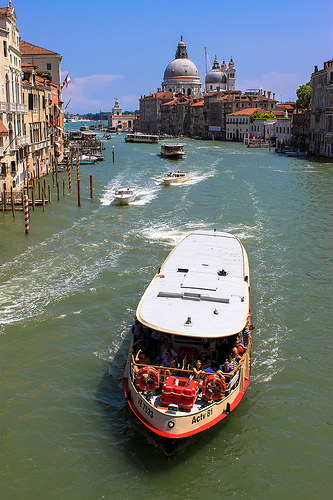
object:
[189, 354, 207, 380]
old woman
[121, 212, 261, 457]
boat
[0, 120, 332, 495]
water